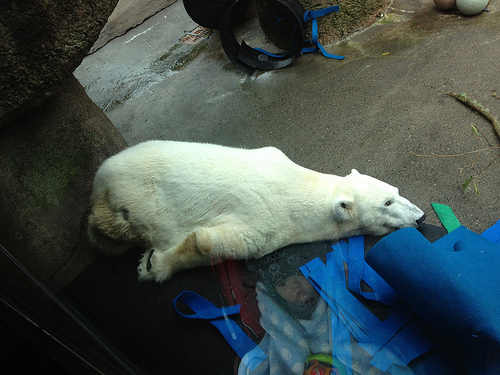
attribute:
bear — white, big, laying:
[86, 138, 428, 286]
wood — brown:
[1, 241, 148, 374]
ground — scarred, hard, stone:
[57, 0, 499, 374]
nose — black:
[415, 212, 426, 224]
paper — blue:
[306, 264, 385, 334]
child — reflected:
[237, 242, 412, 374]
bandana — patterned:
[255, 241, 316, 287]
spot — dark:
[174, 228, 212, 264]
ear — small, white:
[333, 197, 356, 220]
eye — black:
[384, 198, 394, 207]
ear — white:
[349, 169, 360, 176]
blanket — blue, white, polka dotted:
[238, 281, 414, 374]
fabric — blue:
[298, 215, 500, 375]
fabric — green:
[431, 200, 463, 235]